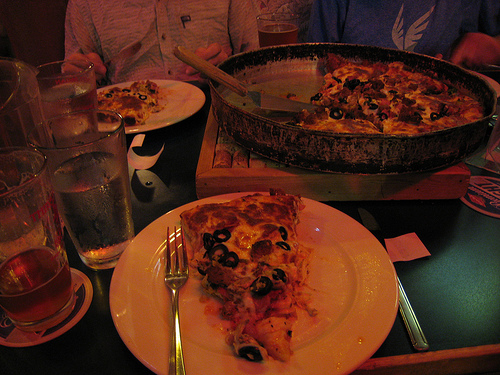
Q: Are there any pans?
A: Yes, there is a pan.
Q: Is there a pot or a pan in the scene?
A: Yes, there is a pan.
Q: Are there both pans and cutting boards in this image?
A: No, there is a pan but no cutting boards.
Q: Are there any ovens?
A: No, there are no ovens.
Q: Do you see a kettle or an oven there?
A: No, there are no ovens or kettles.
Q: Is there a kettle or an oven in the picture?
A: No, there are no ovens or kettles.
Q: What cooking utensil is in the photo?
A: The cooking utensil is a pan.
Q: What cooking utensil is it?
A: The cooking utensil is a pan.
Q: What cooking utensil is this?
A: This is a pan.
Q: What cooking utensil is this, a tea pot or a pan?
A: This is a pan.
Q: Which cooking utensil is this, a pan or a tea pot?
A: This is a pan.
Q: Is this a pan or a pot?
A: This is a pan.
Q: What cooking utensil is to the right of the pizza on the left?
A: The cooking utensil is a pan.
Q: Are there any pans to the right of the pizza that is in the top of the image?
A: Yes, there is a pan to the right of the pizza.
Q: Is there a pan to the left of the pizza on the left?
A: No, the pan is to the right of the pizza.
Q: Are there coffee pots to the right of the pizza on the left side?
A: No, there is a pan to the right of the pizza.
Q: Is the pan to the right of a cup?
A: No, the pan is to the right of the pizza.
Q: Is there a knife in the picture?
A: Yes, there is a knife.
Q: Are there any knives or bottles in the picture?
A: Yes, there is a knife.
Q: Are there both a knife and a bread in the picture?
A: No, there is a knife but no breads.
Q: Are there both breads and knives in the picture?
A: No, there is a knife but no breads.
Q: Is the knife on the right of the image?
A: Yes, the knife is on the right of the image.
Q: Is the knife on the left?
A: No, the knife is on the right of the image.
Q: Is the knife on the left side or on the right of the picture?
A: The knife is on the right of the image.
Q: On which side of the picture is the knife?
A: The knife is on the right of the image.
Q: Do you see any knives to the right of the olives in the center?
A: Yes, there is a knife to the right of the olives.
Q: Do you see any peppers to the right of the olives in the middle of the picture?
A: No, there is a knife to the right of the olives.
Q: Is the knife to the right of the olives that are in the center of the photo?
A: Yes, the knife is to the right of the olives.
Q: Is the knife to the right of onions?
A: No, the knife is to the right of the olives.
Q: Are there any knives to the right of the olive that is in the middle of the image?
A: Yes, there is a knife to the right of the olive.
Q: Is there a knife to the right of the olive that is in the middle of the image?
A: Yes, there is a knife to the right of the olive.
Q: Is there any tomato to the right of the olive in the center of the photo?
A: No, there is a knife to the right of the olive.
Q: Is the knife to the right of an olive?
A: Yes, the knife is to the right of an olive.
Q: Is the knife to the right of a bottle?
A: No, the knife is to the right of an olive.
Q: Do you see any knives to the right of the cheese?
A: Yes, there is a knife to the right of the cheese.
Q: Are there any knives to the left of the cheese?
A: No, the knife is to the right of the cheese.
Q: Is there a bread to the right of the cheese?
A: No, there is a knife to the right of the cheese.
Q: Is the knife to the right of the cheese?
A: Yes, the knife is to the right of the cheese.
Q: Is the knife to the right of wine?
A: No, the knife is to the right of the cheese.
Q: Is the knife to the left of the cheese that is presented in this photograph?
A: No, the knife is to the right of the cheese.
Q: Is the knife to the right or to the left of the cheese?
A: The knife is to the right of the cheese.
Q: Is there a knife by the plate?
A: Yes, there is a knife by the plate.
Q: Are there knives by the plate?
A: Yes, there is a knife by the plate.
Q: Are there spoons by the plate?
A: No, there is a knife by the plate.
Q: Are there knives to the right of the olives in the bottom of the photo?
A: Yes, there is a knife to the right of the olives.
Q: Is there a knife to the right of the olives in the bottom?
A: Yes, there is a knife to the right of the olives.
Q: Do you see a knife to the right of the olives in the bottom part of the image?
A: Yes, there is a knife to the right of the olives.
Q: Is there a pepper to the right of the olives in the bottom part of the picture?
A: No, there is a knife to the right of the olives.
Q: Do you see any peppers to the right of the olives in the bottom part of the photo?
A: No, there is a knife to the right of the olives.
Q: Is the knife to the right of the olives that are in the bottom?
A: Yes, the knife is to the right of the olives.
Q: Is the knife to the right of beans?
A: No, the knife is to the right of the olives.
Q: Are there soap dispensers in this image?
A: No, there are no soap dispensers.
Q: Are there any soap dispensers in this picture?
A: No, there are no soap dispensers.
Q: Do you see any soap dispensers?
A: No, there are no soap dispensers.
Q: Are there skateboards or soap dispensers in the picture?
A: No, there are no soap dispensers or skateboards.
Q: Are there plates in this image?
A: Yes, there is a plate.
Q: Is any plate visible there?
A: Yes, there is a plate.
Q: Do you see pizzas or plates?
A: Yes, there is a plate.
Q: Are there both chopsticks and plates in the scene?
A: No, there is a plate but no chopsticks.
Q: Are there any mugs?
A: No, there are no mugs.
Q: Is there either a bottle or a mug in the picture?
A: No, there are no mugs or bottles.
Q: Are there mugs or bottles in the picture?
A: No, there are no mugs or bottles.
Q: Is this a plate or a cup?
A: This is a plate.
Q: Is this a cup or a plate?
A: This is a plate.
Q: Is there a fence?
A: No, there are no fences.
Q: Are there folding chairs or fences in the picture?
A: No, there are no fences or folding chairs.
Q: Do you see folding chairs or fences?
A: No, there are no fences or folding chairs.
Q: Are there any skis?
A: No, there are no skis.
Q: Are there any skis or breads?
A: No, there are no skis or breads.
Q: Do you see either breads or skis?
A: No, there are no skis or breads.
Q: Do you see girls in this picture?
A: No, there are no girls.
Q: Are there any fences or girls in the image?
A: No, there are no girls or fences.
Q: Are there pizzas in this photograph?
A: Yes, there is a pizza.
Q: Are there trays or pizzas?
A: Yes, there is a pizza.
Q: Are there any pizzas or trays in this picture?
A: Yes, there is a pizza.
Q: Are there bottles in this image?
A: No, there are no bottles.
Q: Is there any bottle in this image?
A: No, there are no bottles.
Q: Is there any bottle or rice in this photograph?
A: No, there are no bottles or rice.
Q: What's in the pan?
A: The pizza is in the pan.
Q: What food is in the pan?
A: The food is a pizza.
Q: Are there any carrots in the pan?
A: No, there is a pizza in the pan.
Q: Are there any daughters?
A: No, there are no daughters.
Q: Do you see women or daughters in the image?
A: No, there are no daughters or women.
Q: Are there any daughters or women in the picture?
A: No, there are no daughters or women.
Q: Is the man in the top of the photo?
A: Yes, the man is in the top of the image.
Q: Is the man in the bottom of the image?
A: No, the man is in the top of the image.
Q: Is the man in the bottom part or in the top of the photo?
A: The man is in the top of the image.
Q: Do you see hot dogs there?
A: No, there are no hot dogs.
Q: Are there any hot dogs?
A: No, there are no hot dogs.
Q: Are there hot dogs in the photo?
A: No, there are no hot dogs.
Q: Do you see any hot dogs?
A: No, there are no hot dogs.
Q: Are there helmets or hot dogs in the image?
A: No, there are no hot dogs or helmets.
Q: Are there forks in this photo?
A: Yes, there is a fork.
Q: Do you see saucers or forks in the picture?
A: Yes, there is a fork.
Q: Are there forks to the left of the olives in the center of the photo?
A: Yes, there is a fork to the left of the olives.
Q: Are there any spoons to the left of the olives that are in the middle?
A: No, there is a fork to the left of the olives.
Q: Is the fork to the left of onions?
A: No, the fork is to the left of the olives.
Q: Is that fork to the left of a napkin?
A: No, the fork is to the left of an olive.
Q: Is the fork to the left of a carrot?
A: No, the fork is to the left of an olive.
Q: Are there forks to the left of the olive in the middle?
A: Yes, there is a fork to the left of the olive.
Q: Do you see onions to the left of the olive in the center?
A: No, there is a fork to the left of the olive.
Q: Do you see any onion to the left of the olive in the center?
A: No, there is a fork to the left of the olive.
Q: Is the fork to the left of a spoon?
A: No, the fork is to the left of an olive.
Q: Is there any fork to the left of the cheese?
A: Yes, there is a fork to the left of the cheese.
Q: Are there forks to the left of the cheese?
A: Yes, there is a fork to the left of the cheese.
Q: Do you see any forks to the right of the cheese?
A: No, the fork is to the left of the cheese.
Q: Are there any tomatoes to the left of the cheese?
A: No, there is a fork to the left of the cheese.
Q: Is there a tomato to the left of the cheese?
A: No, there is a fork to the left of the cheese.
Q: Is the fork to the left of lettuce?
A: No, the fork is to the left of the cheese.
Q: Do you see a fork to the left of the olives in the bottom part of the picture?
A: Yes, there is a fork to the left of the olives.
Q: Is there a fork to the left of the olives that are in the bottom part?
A: Yes, there is a fork to the left of the olives.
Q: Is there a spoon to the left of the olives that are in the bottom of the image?
A: No, there is a fork to the left of the olives.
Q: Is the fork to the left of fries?
A: No, the fork is to the left of the olives.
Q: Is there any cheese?
A: Yes, there is cheese.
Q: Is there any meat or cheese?
A: Yes, there is cheese.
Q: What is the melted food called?
A: The food is cheese.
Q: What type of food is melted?
A: The food is cheese.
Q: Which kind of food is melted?
A: The food is cheese.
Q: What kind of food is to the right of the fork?
A: The food is cheese.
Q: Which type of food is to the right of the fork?
A: The food is cheese.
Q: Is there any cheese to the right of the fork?
A: Yes, there is cheese to the right of the fork.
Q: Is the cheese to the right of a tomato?
A: No, the cheese is to the right of the fork.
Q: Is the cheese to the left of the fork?
A: No, the cheese is to the right of the fork.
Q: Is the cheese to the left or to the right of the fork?
A: The cheese is to the right of the fork.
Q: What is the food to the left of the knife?
A: The food is cheese.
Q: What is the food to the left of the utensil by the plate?
A: The food is cheese.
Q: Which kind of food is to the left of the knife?
A: The food is cheese.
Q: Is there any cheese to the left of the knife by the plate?
A: Yes, there is cheese to the left of the knife.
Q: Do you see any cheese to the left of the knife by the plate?
A: Yes, there is cheese to the left of the knife.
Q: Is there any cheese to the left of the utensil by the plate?
A: Yes, there is cheese to the left of the knife.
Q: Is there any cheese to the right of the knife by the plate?
A: No, the cheese is to the left of the knife.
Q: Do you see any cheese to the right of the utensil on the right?
A: No, the cheese is to the left of the knife.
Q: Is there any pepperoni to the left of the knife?
A: No, there is cheese to the left of the knife.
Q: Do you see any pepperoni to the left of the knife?
A: No, there is cheese to the left of the knife.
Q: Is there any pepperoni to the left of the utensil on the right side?
A: No, there is cheese to the left of the knife.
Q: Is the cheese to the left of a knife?
A: Yes, the cheese is to the left of a knife.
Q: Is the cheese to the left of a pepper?
A: No, the cheese is to the left of a knife.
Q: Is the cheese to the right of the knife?
A: No, the cheese is to the left of the knife.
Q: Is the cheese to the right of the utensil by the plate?
A: No, the cheese is to the left of the knife.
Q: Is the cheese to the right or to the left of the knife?
A: The cheese is to the left of the knife.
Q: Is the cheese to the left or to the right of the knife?
A: The cheese is to the left of the knife.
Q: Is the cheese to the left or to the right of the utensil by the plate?
A: The cheese is to the left of the knife.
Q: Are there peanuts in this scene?
A: No, there are no peanuts.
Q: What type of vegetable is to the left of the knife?
A: The vegetable is an olive.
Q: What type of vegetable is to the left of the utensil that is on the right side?
A: The vegetable is an olive.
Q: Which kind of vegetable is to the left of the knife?
A: The vegetable is an olive.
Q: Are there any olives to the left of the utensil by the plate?
A: Yes, there is an olive to the left of the knife.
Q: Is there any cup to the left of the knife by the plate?
A: No, there is an olive to the left of the knife.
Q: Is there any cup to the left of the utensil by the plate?
A: No, there is an olive to the left of the knife.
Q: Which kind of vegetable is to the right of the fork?
A: The vegetable is an olive.